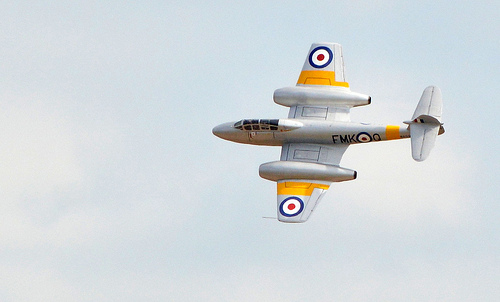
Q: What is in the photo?
A: A plane.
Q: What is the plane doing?
A: Flying.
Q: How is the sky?
A: Clear.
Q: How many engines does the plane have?
A: Two.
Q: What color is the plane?
A: Silver.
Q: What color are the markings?
A: Yellow, red, white, and blue.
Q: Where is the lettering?
A: Along the fuselage.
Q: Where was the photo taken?
A: In the sky.